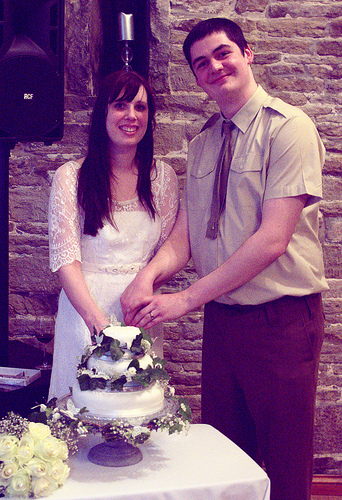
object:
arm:
[179, 114, 323, 313]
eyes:
[112, 98, 126, 113]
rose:
[0, 451, 26, 486]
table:
[39, 421, 274, 499]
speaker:
[0, 0, 69, 151]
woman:
[44, 68, 183, 408]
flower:
[92, 332, 106, 351]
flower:
[177, 399, 189, 413]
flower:
[158, 398, 193, 434]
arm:
[45, 161, 102, 326]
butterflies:
[57, 394, 81, 422]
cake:
[67, 312, 175, 420]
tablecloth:
[43, 420, 271, 500]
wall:
[0, 3, 342, 500]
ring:
[149, 311, 154, 323]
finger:
[125, 295, 152, 314]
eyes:
[195, 58, 209, 73]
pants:
[201, 293, 326, 499]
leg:
[201, 364, 259, 466]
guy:
[119, 14, 329, 499]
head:
[181, 12, 255, 103]